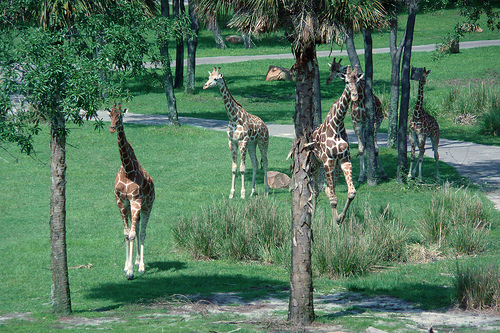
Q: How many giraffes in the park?
A: Five.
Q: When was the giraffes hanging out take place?
A: Daytime.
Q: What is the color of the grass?
A: Green.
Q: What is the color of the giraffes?
A: Brown and white.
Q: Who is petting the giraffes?
A: No one.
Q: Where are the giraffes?
A: At the park.